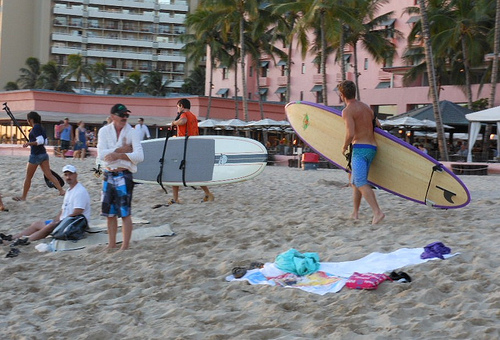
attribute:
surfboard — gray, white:
[133, 136, 268, 185]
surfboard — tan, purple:
[283, 101, 471, 212]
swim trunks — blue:
[349, 143, 377, 187]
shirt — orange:
[175, 112, 200, 137]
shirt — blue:
[59, 122, 72, 142]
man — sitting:
[2, 164, 94, 245]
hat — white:
[62, 164, 78, 175]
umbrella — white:
[382, 111, 422, 128]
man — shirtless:
[336, 80, 386, 227]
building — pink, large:
[203, 3, 499, 151]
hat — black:
[107, 102, 131, 116]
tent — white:
[465, 104, 500, 160]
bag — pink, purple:
[346, 271, 389, 293]